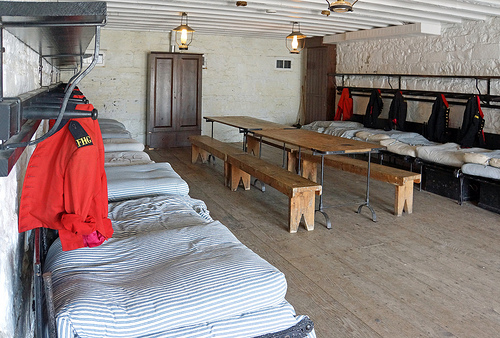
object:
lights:
[173, 13, 194, 49]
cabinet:
[144, 53, 204, 149]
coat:
[333, 87, 353, 120]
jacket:
[17, 103, 112, 251]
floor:
[152, 147, 496, 338]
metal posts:
[341, 74, 346, 94]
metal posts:
[397, 76, 402, 90]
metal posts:
[485, 79, 490, 107]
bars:
[329, 70, 499, 79]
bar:
[336, 83, 499, 106]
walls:
[367, 19, 497, 111]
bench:
[187, 135, 324, 235]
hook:
[61, 108, 98, 120]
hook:
[67, 100, 91, 107]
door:
[143, 51, 204, 148]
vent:
[86, 1, 483, 43]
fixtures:
[169, 12, 312, 57]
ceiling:
[71, 0, 498, 38]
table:
[183, 111, 428, 230]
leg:
[314, 154, 333, 231]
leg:
[356, 152, 378, 224]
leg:
[252, 137, 266, 194]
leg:
[207, 120, 216, 164]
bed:
[461, 149, 500, 211]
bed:
[98, 138, 149, 154]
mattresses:
[47, 196, 303, 336]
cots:
[367, 128, 463, 163]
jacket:
[335, 88, 355, 122]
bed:
[379, 131, 441, 159]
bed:
[418, 143, 478, 202]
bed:
[305, 116, 357, 140]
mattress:
[105, 163, 189, 203]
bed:
[47, 194, 320, 338]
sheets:
[48, 192, 309, 338]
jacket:
[425, 93, 452, 144]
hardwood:
[340, 230, 476, 294]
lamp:
[286, 31, 307, 54]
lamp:
[169, 24, 195, 50]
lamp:
[319, 0, 359, 16]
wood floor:
[143, 141, 498, 336]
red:
[17, 104, 113, 250]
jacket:
[362, 90, 383, 128]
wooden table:
[202, 114, 387, 230]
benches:
[239, 129, 423, 217]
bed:
[104, 162, 187, 203]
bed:
[99, 118, 125, 135]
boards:
[148, 142, 498, 336]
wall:
[61, 25, 303, 154]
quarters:
[0, 0, 499, 338]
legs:
[297, 148, 301, 178]